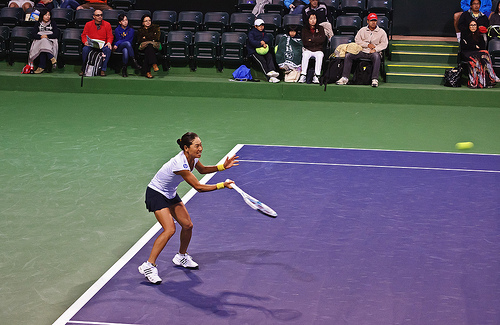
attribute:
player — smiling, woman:
[136, 130, 239, 286]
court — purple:
[2, 65, 499, 325]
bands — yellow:
[216, 164, 225, 172]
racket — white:
[227, 180, 280, 224]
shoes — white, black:
[136, 261, 161, 284]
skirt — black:
[144, 185, 185, 212]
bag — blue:
[228, 64, 252, 83]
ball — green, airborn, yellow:
[455, 140, 473, 152]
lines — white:
[237, 141, 500, 157]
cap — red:
[368, 12, 378, 22]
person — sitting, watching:
[335, 12, 389, 88]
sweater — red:
[81, 18, 114, 47]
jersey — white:
[147, 149, 200, 201]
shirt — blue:
[112, 24, 132, 48]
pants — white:
[301, 46, 325, 78]